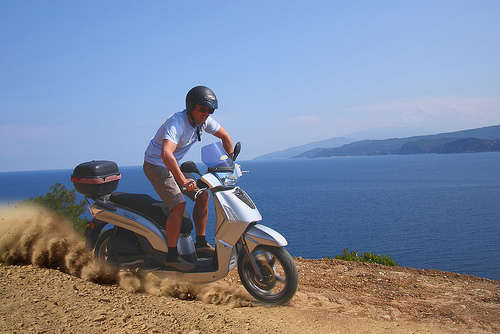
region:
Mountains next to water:
[251, 118, 499, 157]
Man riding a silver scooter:
[65, 80, 300, 304]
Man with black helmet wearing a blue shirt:
[141, 83, 238, 180]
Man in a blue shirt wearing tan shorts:
[141, 84, 236, 274]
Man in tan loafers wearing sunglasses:
[141, 84, 229, 275]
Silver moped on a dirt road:
[71, 140, 300, 305]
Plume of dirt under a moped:
[0, 196, 262, 311]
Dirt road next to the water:
[1, 251, 499, 331]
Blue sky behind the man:
[0, 2, 498, 169]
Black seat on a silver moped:
[107, 190, 195, 239]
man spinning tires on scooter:
[65, 83, 303, 312]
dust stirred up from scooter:
[6, 202, 100, 276]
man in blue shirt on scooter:
[69, 87, 306, 307]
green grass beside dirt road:
[334, 245, 396, 272]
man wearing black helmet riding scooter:
[67, 83, 300, 303]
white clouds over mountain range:
[343, 94, 475, 131]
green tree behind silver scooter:
[17, 182, 94, 249]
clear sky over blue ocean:
[12, 48, 122, 150]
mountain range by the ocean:
[305, 127, 490, 158]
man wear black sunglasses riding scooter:
[191, 103, 221, 115]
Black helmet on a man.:
[184, 85, 217, 122]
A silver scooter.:
[69, 141, 298, 303]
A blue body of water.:
[1, 156, 498, 281]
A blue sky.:
[0, 2, 498, 160]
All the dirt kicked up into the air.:
[2, 203, 249, 307]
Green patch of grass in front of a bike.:
[340, 247, 397, 267]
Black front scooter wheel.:
[237, 242, 298, 304]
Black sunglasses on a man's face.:
[193, 102, 214, 114]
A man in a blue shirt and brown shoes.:
[142, 86, 237, 271]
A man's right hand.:
[178, 178, 199, 191]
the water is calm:
[295, 173, 420, 253]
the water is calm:
[312, 160, 452, 236]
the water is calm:
[267, 111, 442, 236]